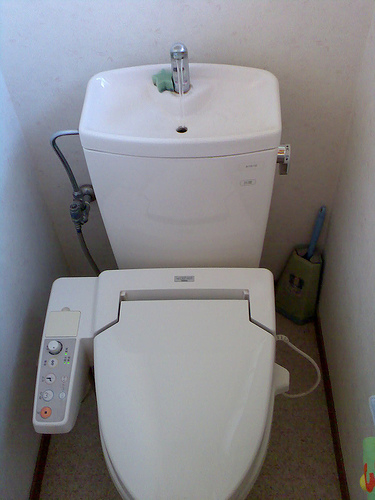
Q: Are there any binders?
A: No, there are no binders.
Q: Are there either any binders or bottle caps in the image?
A: No, there are no binders or bottle caps.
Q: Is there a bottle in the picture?
A: No, there are no bottles.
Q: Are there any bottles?
A: No, there are no bottles.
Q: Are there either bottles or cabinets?
A: No, there are no bottles or cabinets.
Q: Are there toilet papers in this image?
A: No, there are no toilet papers.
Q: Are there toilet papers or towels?
A: No, there are no toilet papers or towels.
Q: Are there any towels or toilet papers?
A: No, there are no toilet papers or towels.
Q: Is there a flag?
A: No, there are no flags.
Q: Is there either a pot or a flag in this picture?
A: No, there are no flags or pots.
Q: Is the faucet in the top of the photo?
A: Yes, the faucet is in the top of the image.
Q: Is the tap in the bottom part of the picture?
A: No, the tap is in the top of the image.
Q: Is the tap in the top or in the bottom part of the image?
A: The tap is in the top of the image.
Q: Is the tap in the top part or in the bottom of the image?
A: The tap is in the top of the image.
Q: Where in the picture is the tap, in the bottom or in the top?
A: The tap is in the top of the image.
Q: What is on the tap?
A: The water is on the tap.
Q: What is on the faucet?
A: The water is on the tap.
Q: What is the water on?
A: The water is on the tap.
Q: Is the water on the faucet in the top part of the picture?
A: Yes, the water is on the tap.